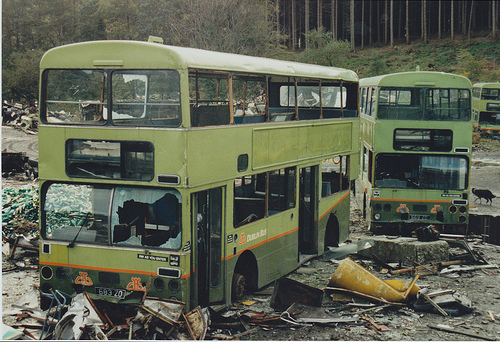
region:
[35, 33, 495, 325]
Three double decker buses.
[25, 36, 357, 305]
The bus is green.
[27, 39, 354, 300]
The bus is old.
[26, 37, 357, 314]
The bus is not in use anymore.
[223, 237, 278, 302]
No tires are on the bus.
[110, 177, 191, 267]
A window on the bus is out.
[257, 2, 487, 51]
Trees are in the background.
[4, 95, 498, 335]
A lot of garbage is on the ground.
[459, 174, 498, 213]
An animal is to the right.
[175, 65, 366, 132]
The top windows are out on the bus.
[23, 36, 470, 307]
A couple of double decker buses.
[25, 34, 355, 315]
The busses are green.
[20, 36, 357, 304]
The busses are old.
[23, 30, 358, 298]
The busses are not in use.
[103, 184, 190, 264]
The window is out of the buss.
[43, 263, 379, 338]
A lot of garbage is on the ground.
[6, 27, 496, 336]
A lot of junk in the picture.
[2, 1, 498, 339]
abandoned green double decker buses in a junk yard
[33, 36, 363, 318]
abandoned olive green double decker bus with broken out windows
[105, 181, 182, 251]
broken bus window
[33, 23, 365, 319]
double decker bus in a junk yard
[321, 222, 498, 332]
lots of junk and debris on the ground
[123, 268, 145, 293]
orange bus logo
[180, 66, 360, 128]
row of broken out windows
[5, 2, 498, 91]
trees, plants, and grass in the background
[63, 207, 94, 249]
bus windshield wiper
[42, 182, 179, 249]
windshield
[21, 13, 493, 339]
three double-decker buses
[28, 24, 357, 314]
green bus with and orange stripe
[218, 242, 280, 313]
tires are missing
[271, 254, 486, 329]
lots of scrap metal on the ground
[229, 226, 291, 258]
writing on the side of the bus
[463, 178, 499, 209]
dog wandering in the scrapyard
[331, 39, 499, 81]
patch of grass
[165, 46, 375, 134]
some windows are broken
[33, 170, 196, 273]
smashed front windshield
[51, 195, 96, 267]
one wiper blade is left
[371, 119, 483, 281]
A bus is visible.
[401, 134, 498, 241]
A bus is visible.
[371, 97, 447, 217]
A bus is visible.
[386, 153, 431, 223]
A bus is visible.